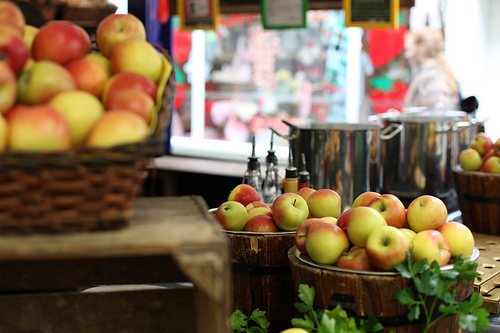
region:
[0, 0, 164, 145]
Apples on the table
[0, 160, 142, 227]
A basket on the table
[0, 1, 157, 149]
Red and green apples on the table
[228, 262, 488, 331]
Green leaves in the photo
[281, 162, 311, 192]
Bottles in the photo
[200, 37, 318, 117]
A window in the background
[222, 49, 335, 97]
Light on the window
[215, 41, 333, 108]
Glass panes on the window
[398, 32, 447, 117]
A person in the background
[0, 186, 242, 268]
A table in the photo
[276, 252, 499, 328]
these are some plants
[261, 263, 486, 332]
the plants are small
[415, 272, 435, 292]
the leaves are green in color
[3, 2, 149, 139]
these are some apples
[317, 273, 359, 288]
this is a bucket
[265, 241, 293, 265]
the bucket is brown in color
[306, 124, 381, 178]
this is a pot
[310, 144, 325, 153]
the pot is metallic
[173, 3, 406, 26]
these are some frames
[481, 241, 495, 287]
this is a table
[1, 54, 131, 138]
A bunch of apples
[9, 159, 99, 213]
A basket containing apples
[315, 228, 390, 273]
Apples in a barrel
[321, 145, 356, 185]
A metallic container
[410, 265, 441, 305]
A green on a barrel side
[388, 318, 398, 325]
A metal strap around a barrel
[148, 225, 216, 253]
A wooden bench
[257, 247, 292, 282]
Two barrels side by side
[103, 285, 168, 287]
Space betwen two wood pieces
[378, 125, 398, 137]
A metallic handle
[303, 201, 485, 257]
the apples are ripe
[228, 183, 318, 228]
the apples are ripe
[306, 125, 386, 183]
the pot is silver in color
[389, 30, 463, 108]
woman is in the background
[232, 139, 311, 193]
four bottles rae on the table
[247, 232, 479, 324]
the basket is wooden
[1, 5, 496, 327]
the scene is in the market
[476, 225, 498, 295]
holes are on the suface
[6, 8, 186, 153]
the apples are piled together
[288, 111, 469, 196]
the pots are mettalic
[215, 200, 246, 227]
a yellow and red apple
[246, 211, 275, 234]
a yellow and red apple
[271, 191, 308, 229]
a yellow and red apple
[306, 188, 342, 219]
a yellow and red apple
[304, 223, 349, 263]
a yellow and red apple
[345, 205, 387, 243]
a yellow and red apple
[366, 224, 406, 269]
a yellow and red apple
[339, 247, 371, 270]
a yellow and red apple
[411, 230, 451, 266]
a yellow and red apple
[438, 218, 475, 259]
a yellow and red apple